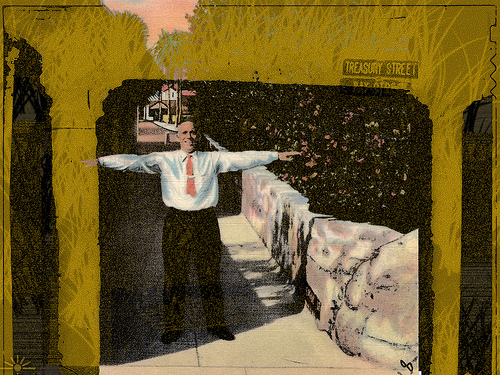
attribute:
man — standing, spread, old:
[124, 130, 287, 355]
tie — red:
[177, 156, 203, 197]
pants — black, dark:
[168, 227, 224, 307]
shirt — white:
[160, 163, 219, 209]